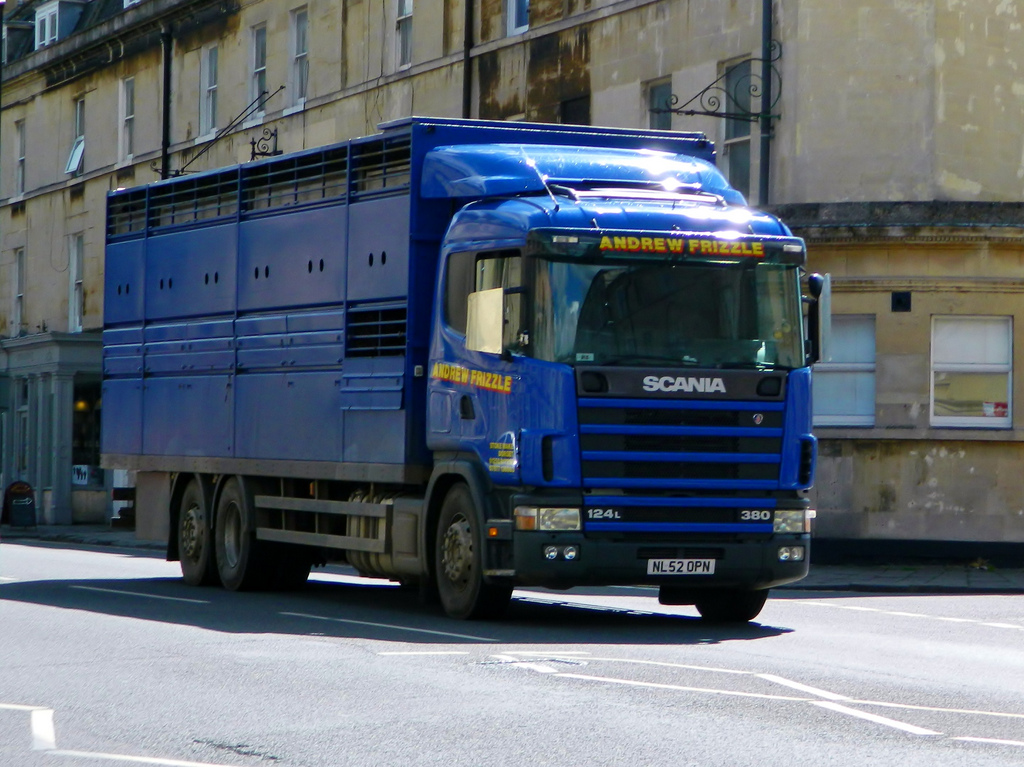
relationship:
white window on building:
[386, 5, 422, 70] [2, 0, 1021, 554]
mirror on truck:
[795, 265, 837, 374] [102, 111, 839, 627]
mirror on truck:
[460, 288, 524, 359] [102, 111, 839, 627]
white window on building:
[805, 313, 877, 427] [2, 0, 1021, 554]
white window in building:
[57, 84, 100, 179] [6, 8, 169, 201]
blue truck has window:
[99, 116, 832, 621] [527, 242, 812, 369]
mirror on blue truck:
[808, 273, 832, 364] [99, 116, 832, 621]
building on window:
[2, 0, 1021, 554] [710, 53, 765, 203]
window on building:
[718, 52, 761, 205] [2, 0, 1021, 554]